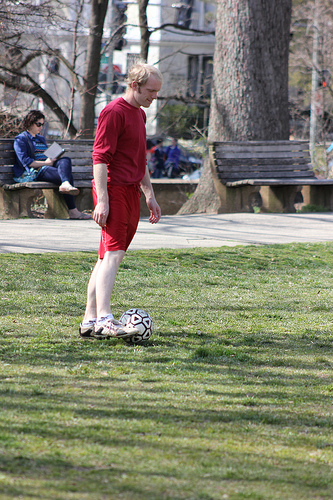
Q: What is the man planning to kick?
A: The soccer ball.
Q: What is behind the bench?
A: A large tree.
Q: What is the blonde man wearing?
A: Red shirt and red shorts.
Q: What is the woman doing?
A: Reading a book.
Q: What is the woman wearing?
A: Sunglasses.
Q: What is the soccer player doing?
A: Kicking the soccer ball.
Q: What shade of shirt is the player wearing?
A: Red.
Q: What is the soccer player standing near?
A: A park bench.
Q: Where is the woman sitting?
A: On the bench.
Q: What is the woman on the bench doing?
A: Reading a book.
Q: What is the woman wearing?
A: Jeans.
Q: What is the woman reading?
A: A book.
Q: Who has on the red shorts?
A: Soccer player.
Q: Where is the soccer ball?
A: On the grass.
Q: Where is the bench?
A: In the park.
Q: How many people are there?
A: Two.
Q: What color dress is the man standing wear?
A: Red.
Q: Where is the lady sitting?
A: Bench.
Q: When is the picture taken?
A: Daytime.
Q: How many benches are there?
A: 2.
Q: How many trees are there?
A: Three.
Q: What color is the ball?
A: Black and white.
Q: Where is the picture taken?
A: In a park.